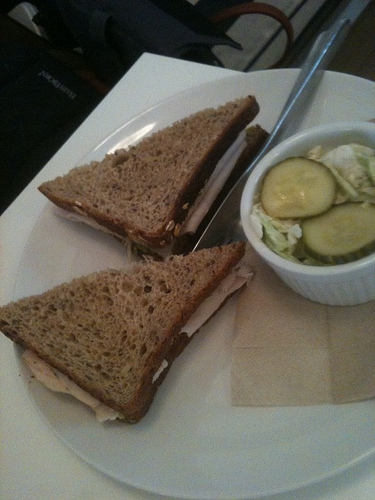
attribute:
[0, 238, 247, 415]
bread — brown, halved, cut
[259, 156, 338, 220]
pickle — green, sliced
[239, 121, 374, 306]
ramekin — white, ceramic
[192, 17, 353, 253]
knife — steel, shiny, metal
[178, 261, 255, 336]
meat — white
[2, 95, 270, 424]
sandwich — halved, triangle, wheat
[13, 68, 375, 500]
plate — white, large, ceramic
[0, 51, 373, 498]
mat — white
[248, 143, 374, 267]
coleslaw — green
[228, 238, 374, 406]
napkin — brown